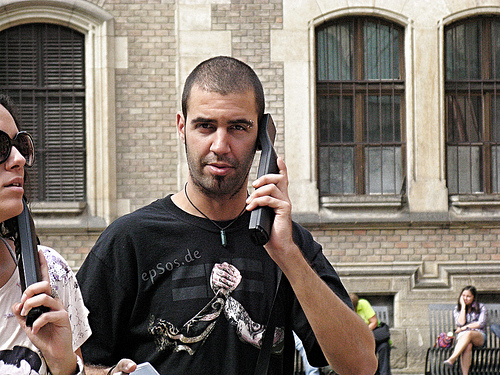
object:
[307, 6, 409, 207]
window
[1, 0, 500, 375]
building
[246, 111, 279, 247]
phone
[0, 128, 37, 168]
sunglasses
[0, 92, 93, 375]
woman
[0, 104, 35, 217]
face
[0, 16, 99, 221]
window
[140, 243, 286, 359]
design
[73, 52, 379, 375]
man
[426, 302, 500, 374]
bench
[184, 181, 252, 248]
black necklace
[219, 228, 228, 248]
pendant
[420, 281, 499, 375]
woman bench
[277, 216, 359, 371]
sleeve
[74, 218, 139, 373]
sleeve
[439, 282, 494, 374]
lady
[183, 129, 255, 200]
facial hair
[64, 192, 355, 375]
black t-shirt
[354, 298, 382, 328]
shirt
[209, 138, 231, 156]
nose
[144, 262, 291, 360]
decal